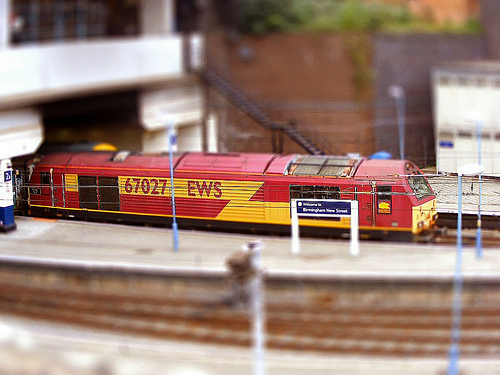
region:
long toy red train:
[20, 144, 442, 238]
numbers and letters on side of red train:
[121, 175, 232, 200]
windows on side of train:
[278, 181, 349, 208]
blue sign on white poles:
[280, 193, 375, 259]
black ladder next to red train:
[184, 55, 329, 156]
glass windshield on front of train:
[401, 167, 436, 202]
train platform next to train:
[8, 216, 473, 286]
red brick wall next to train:
[231, 31, 408, 154]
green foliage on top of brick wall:
[187, 0, 444, 29]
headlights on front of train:
[413, 205, 443, 236]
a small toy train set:
[57, 118, 434, 248]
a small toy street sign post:
[155, 136, 195, 244]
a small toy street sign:
[161, 125, 182, 152]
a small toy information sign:
[278, 191, 375, 255]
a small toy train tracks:
[454, 215, 494, 250]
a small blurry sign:
[222, 268, 284, 366]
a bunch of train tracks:
[137, 265, 211, 363]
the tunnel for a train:
[38, 38, 163, 140]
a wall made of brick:
[244, 43, 372, 150]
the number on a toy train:
[114, 163, 231, 211]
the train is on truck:
[107, 140, 447, 290]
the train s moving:
[57, 145, 399, 294]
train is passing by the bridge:
[1, 54, 169, 250]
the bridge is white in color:
[17, 28, 260, 134]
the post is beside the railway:
[138, 126, 203, 282]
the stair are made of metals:
[200, 51, 327, 174]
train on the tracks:
[11, 133, 481, 248]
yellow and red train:
[18, 138, 459, 250]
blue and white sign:
[289, 195, 361, 218]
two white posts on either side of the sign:
[285, 195, 374, 257]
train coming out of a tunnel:
[1, 45, 458, 254]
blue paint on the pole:
[450, 174, 467, 373]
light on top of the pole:
[455, 160, 485, 177]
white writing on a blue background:
[295, 197, 350, 219]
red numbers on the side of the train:
[118, 170, 169, 197]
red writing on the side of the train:
[182, 178, 228, 200]